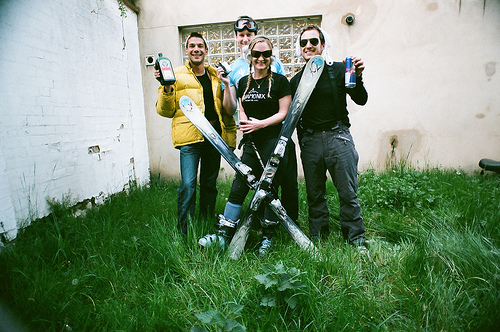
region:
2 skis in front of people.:
[191, 94, 332, 308]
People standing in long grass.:
[151, 135, 435, 291]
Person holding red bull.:
[333, 65, 358, 146]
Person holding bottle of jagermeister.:
[156, 53, 189, 104]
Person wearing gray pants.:
[325, 184, 381, 230]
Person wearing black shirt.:
[292, 67, 357, 147]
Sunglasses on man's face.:
[296, 32, 313, 52]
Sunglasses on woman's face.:
[256, 35, 281, 92]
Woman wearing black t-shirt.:
[239, 87, 281, 162]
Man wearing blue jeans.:
[174, 145, 234, 265]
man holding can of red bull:
[286, 25, 378, 253]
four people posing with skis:
[146, 17, 387, 264]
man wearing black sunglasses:
[290, 25, 330, 67]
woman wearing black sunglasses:
[241, 33, 278, 103]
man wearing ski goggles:
[228, 13, 261, 53]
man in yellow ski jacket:
[156, 31, 231, 236]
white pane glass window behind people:
[173, 11, 348, 93]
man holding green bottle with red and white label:
[152, 30, 227, 241]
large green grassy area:
[0, 182, 499, 324]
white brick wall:
[5, 1, 161, 238]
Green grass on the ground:
[1, 141, 498, 330]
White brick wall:
[0, 0, 152, 242]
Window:
[178, 12, 325, 82]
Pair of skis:
[178, 51, 328, 261]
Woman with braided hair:
[197, 34, 292, 261]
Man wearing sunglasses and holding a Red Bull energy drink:
[289, 25, 370, 255]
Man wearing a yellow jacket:
[154, 30, 237, 238]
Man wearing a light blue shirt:
[216, 15, 298, 233]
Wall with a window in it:
[137, 0, 499, 182]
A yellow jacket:
[156, 59, 237, 149]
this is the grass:
[48, 226, 119, 294]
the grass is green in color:
[75, 241, 145, 319]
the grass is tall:
[150, 246, 212, 324]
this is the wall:
[397, 43, 454, 88]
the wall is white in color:
[391, 62, 457, 102]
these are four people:
[144, 22, 378, 219]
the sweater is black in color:
[313, 94, 338, 123]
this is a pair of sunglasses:
[298, 37, 322, 48]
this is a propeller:
[186, 60, 321, 245]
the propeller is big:
[185, 60, 323, 250]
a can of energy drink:
[340, 54, 357, 89]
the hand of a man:
[340, 52, 369, 75]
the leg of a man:
[326, 132, 368, 245]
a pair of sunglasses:
[296, 33, 323, 49]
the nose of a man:
[304, 38, 313, 49]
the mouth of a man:
[300, 47, 317, 58]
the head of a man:
[295, 22, 330, 64]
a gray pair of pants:
[301, 123, 367, 245]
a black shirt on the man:
[286, 55, 371, 133]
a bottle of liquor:
[149, 46, 181, 89]